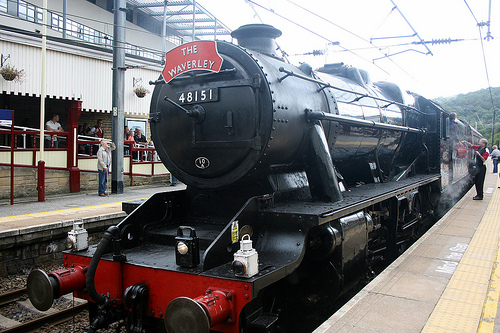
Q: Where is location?
A: A train terminal.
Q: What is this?
A: A train.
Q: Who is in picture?
A: People.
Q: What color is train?
A: Black.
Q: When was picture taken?
A: During daylight.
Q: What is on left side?
A: Train terminal.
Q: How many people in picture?
A: Five.